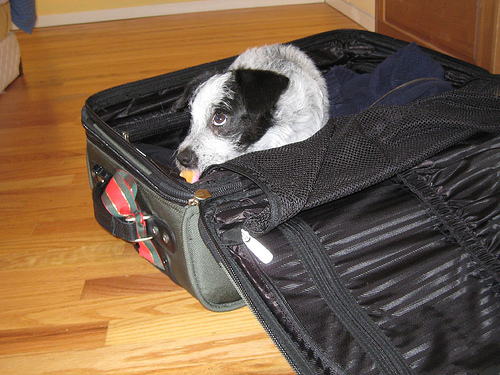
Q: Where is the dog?
A: On the suitcase.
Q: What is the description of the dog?
A: Black and white.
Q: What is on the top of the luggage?
A: A green and red ribbon.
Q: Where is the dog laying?
A: On top of clothes.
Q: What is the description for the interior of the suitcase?
A: It is black.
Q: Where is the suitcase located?
A: On the floor.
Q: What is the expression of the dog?
A: Sad.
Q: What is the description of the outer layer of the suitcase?
A: Olive green.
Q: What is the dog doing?
A: Laying down in the suitcase.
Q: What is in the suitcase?
A: Dog.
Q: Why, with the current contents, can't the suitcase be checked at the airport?
A: The dog will be harmed.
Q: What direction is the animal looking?
A: Upward.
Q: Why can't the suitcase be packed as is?
A: The dog is in the way.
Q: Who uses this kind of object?
A: Travelers.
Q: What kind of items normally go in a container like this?
A: Clothing, toiletries, shoes.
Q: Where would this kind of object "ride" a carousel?
A: Baggage claim.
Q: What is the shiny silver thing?
A: Zipper tab.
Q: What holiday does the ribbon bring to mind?
A: Christmas.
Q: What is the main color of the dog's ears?
A: Black.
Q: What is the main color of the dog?
A: White.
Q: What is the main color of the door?
A: Brown.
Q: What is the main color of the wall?
A: Yellow.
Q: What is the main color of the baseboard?
A: White.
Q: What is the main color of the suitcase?
A: Black.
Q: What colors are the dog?
A: Black and white.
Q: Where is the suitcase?
A: On the floor.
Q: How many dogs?
A: One.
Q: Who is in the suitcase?
A: A dog.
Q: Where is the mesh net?
A: The suitcase.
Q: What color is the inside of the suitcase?
A: Black.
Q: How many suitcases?
A: One.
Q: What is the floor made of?
A: Wood.